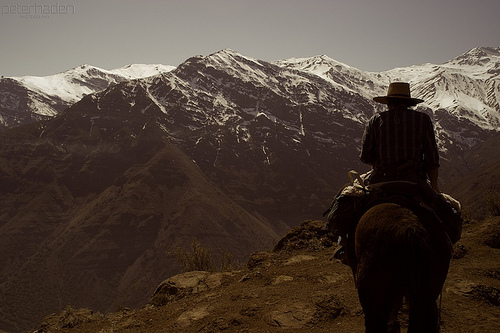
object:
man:
[355, 80, 445, 188]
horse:
[322, 179, 470, 333]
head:
[385, 82, 419, 110]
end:
[358, 216, 447, 302]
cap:
[372, 81, 425, 105]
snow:
[305, 56, 333, 71]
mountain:
[138, 48, 341, 108]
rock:
[152, 271, 230, 295]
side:
[197, 165, 220, 192]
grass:
[36, 304, 100, 320]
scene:
[239, 89, 475, 239]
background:
[62, 30, 463, 288]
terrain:
[184, 230, 500, 333]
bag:
[325, 175, 370, 235]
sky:
[1, 0, 500, 45]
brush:
[163, 236, 240, 276]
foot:
[328, 235, 352, 263]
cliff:
[208, 222, 302, 296]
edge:
[233, 252, 282, 294]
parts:
[399, 287, 443, 314]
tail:
[380, 229, 433, 312]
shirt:
[359, 110, 444, 170]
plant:
[163, 234, 213, 272]